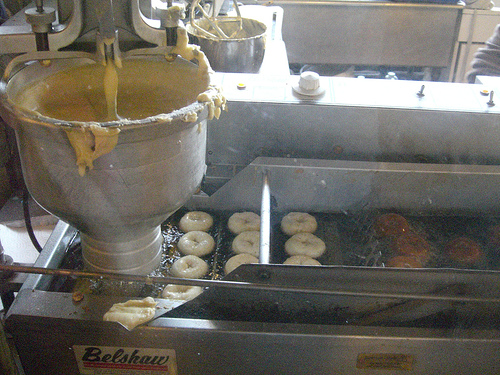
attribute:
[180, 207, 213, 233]
donut — not fried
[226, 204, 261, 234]
donut — not fried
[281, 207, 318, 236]
donut — not fried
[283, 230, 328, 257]
donut — not fried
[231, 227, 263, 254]
donut — not fried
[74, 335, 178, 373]
name — belshaw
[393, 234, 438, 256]
donut — glazed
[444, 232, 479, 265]
donut — glazed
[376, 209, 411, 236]
donut — glazed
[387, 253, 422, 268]
donut — glazed